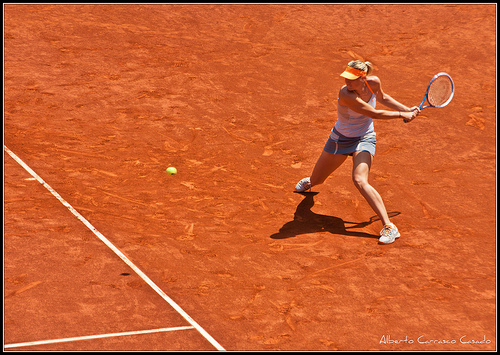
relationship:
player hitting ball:
[293, 58, 421, 245] [165, 163, 178, 178]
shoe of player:
[293, 174, 317, 194] [241, 39, 491, 263]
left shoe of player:
[377, 225, 399, 242] [293, 58, 421, 245]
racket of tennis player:
[403, 69, 456, 122] [262, 47, 416, 254]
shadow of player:
[270, 189, 379, 246] [293, 58, 421, 245]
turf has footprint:
[8, 6, 495, 351] [183, 178, 203, 192]